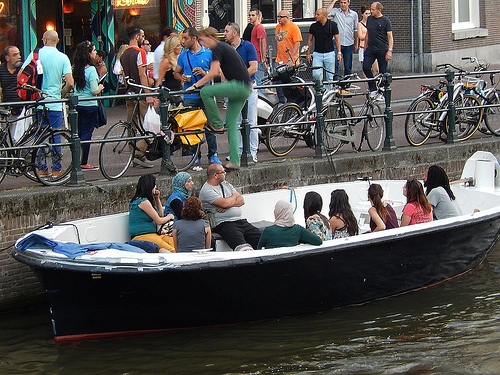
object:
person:
[362, 0, 395, 92]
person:
[15, 29, 74, 178]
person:
[73, 40, 106, 171]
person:
[127, 173, 176, 253]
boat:
[10, 151, 499, 340]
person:
[171, 194, 213, 256]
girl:
[329, 190, 358, 240]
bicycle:
[0, 81, 73, 186]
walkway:
[0, 63, 499, 191]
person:
[187, 28, 251, 172]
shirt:
[23, 46, 73, 113]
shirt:
[74, 65, 101, 106]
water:
[2, 238, 498, 374]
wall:
[0, 201, 133, 300]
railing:
[0, 68, 500, 107]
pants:
[198, 79, 253, 167]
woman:
[255, 201, 323, 250]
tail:
[371, 193, 392, 223]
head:
[366, 183, 384, 203]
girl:
[300, 191, 333, 242]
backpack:
[14, 50, 44, 103]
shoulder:
[25, 47, 44, 62]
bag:
[142, 104, 162, 135]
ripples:
[350, 317, 379, 329]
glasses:
[276, 15, 288, 19]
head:
[277, 8, 290, 25]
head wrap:
[273, 199, 295, 227]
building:
[350, 1, 498, 73]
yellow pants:
[132, 233, 176, 253]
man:
[275, 9, 303, 105]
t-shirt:
[275, 22, 302, 65]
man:
[198, 163, 260, 250]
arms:
[199, 188, 237, 208]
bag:
[168, 105, 207, 146]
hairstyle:
[367, 183, 392, 224]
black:
[363, 15, 394, 94]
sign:
[113, 0, 151, 8]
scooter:
[256, 44, 317, 148]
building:
[174, 0, 334, 70]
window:
[451, 0, 482, 31]